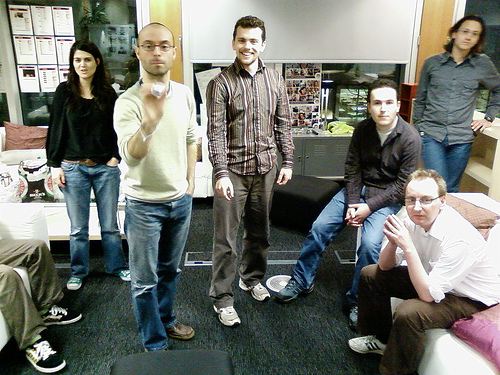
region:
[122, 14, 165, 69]
man has short hair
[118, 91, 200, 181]
man has cream colored shirt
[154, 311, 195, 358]
man has brown shoes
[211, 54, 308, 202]
brown and red shirt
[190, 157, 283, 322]
man has brown pants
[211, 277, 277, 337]
grey and white shoes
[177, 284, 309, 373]
men on dark green carpet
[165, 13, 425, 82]
white wall behind men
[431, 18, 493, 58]
man has long brown hair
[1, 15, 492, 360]
The people are inside an office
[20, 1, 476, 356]
Some people are inside a room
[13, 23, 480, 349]
The people are all gathered together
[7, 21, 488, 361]
The people are friends and coworkers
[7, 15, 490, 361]
The people are all watching something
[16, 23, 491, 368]
The people work in the same office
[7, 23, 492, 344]
The people are all very relaxed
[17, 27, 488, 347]
The people are part of a social group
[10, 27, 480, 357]
The people are out in the daytime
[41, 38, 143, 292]
woman in black shirt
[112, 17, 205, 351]
man in white sweater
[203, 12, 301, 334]
man in striped shirt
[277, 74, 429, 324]
man in brown button down shirt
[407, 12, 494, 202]
man in gray button down shirt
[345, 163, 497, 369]
man in white button down shirt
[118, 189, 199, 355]
men's blue denim pants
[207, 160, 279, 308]
men's brown corduroy slacks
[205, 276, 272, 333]
men's white athletic footwear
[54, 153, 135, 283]
ladies blue denim jeans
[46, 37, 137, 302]
a woman behind the man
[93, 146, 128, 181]
her hand is in her pocket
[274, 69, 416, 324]
a man sitting down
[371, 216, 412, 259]
his hands are foldid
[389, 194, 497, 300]
this shirt is white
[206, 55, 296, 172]
this shirt is striped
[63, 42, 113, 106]
her hair is dark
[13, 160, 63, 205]
a pillow on the sofa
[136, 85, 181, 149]
person holding a wii controller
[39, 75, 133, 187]
woman wearing a black shirt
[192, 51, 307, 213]
man wearing a striped shirt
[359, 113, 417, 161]
man wearing a collared shirt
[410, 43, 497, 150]
man wearing a grey shirt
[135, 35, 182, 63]
man wearing thin glasses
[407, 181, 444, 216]
man wearing thin glasses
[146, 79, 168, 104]
man holding paper wad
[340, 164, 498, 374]
man sitting on white couch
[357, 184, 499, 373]
couch under man is white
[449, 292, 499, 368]
pillow on couch is purple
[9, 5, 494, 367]
a group of people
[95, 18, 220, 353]
man holding a wii remote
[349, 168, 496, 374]
a man sitting down